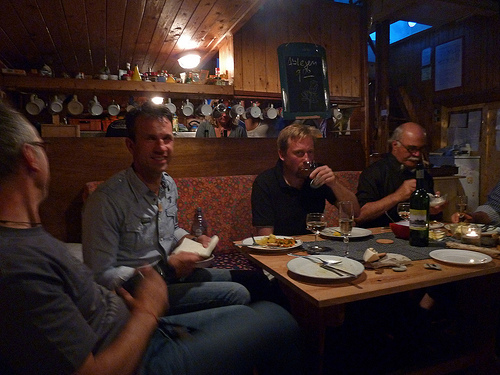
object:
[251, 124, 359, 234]
man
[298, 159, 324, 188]
glass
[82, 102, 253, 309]
man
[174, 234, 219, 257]
napkin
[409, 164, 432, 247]
wine bottle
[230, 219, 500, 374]
table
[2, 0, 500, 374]
restaurant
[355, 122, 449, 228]
man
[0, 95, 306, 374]
man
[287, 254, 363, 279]
plate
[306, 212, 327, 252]
wine glass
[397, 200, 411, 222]
wine glass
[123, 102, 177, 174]
head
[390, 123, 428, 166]
head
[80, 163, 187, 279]
shirt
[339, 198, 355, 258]
champagne glass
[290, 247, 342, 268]
fork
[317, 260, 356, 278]
knife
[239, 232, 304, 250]
plate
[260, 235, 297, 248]
food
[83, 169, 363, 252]
bench back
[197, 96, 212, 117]
mug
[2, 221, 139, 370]
shirt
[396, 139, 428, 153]
glasses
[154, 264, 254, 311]
jeans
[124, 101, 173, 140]
hair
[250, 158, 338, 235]
shirt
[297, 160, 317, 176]
drink